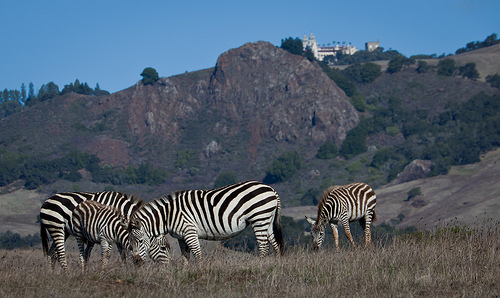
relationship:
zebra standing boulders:
[297, 179, 383, 262] [25, 50, 446, 167]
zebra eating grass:
[297, 179, 383, 262] [203, 250, 399, 281]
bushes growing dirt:
[264, 137, 450, 176] [403, 181, 473, 211]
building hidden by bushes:
[363, 37, 381, 51] [348, 47, 409, 63]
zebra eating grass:
[33, 189, 170, 282] [2, 230, 476, 294]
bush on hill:
[339, 119, 370, 163] [270, 76, 484, 211]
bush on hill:
[262, 149, 312, 188] [252, 61, 471, 210]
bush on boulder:
[280, 35, 304, 55] [195, 40, 360, 150]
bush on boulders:
[367, 148, 390, 169] [0, 72, 183, 167]